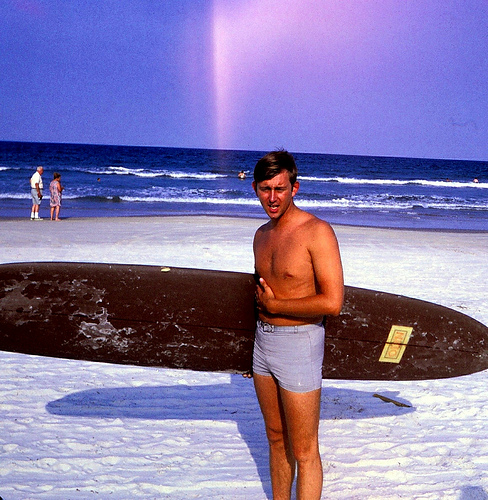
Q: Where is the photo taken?
A: Beach.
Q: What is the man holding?
A: Surfboard.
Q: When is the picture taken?
A: Daytime.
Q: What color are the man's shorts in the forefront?
A: Blue.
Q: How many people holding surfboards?
A: One.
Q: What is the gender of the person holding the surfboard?
A: Male.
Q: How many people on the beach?
A: Three.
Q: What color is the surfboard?
A: Brown.